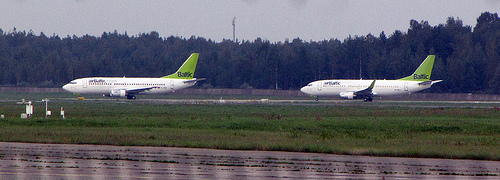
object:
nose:
[61, 75, 85, 92]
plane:
[57, 48, 205, 106]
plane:
[290, 51, 447, 108]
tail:
[164, 52, 204, 82]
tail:
[406, 52, 446, 83]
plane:
[305, 69, 437, 114]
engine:
[338, 94, 359, 101]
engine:
[108, 85, 128, 97]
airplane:
[300, 55, 445, 103]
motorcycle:
[361, 88, 381, 107]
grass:
[128, 81, 451, 145]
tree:
[445, 21, 480, 95]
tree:
[408, 19, 427, 83]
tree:
[475, 16, 497, 85]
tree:
[282, 42, 303, 90]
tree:
[349, 38, 366, 80]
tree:
[341, 37, 363, 79]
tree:
[230, 39, 262, 89]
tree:
[98, 33, 122, 75]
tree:
[35, 35, 61, 80]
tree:
[295, 49, 315, 96]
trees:
[10, 15, 497, 90]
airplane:
[60, 52, 206, 100]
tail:
[408, 49, 440, 79]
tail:
[168, 50, 199, 77]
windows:
[99, 78, 174, 87]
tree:
[285, 36, 301, 99]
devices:
[13, 97, 66, 121]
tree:
[362, 35, 392, 81]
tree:
[407, 18, 435, 80]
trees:
[7, 16, 499, 51]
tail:
[395, 53, 437, 82]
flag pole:
[217, 10, 252, 71]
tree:
[4, 38, 43, 83]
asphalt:
[283, 102, 486, 107]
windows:
[87, 79, 167, 87]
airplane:
[287, 51, 444, 103]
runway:
[0, 89, 499, 104]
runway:
[4, 92, 497, 178]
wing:
[127, 88, 157, 98]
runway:
[3, 88, 493, 107]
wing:
[121, 84, 157, 95]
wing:
[357, 81, 373, 100]